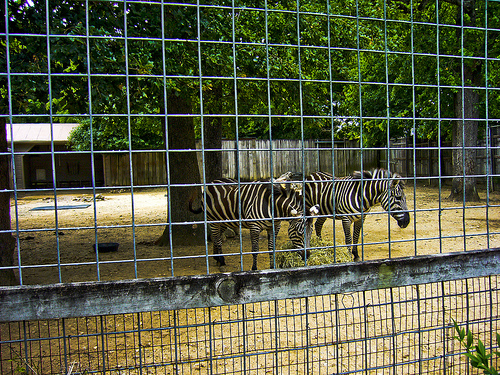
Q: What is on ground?
A: Hay.